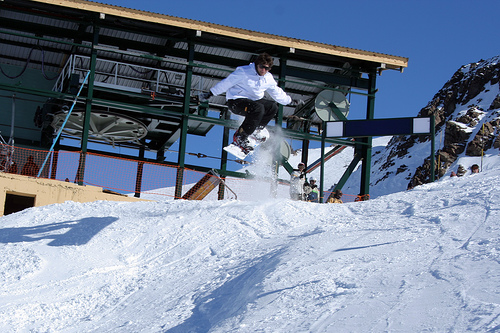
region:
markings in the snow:
[156, 198, 451, 331]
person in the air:
[211, 61, 301, 173]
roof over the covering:
[84, 0, 403, 62]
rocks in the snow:
[426, 73, 496, 176]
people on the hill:
[295, 161, 357, 218]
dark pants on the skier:
[227, 105, 269, 133]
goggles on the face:
[258, 65, 269, 74]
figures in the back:
[1, 146, 64, 182]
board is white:
[231, 130, 283, 156]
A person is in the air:
[185, 35, 286, 275]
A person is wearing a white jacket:
[196, 31, 303, 147]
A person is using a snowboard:
[187, 37, 279, 182]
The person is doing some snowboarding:
[185, 32, 290, 307]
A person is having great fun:
[186, 22, 286, 322]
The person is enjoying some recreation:
[195, 13, 287, 324]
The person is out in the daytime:
[178, 27, 283, 324]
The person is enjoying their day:
[196, 30, 286, 331]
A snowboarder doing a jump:
[200, 47, 305, 159]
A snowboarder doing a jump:
[196, 48, 306, 163]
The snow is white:
[13, 216, 498, 310]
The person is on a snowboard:
[201, 43, 304, 176]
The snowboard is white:
[219, 114, 286, 161]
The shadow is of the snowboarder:
[2, 190, 123, 267]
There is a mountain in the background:
[343, 50, 498, 175]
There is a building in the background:
[2, 0, 423, 221]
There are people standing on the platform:
[1, 137, 172, 207]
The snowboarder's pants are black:
[224, 89, 284, 155]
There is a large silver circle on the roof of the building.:
[44, 90, 170, 165]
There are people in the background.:
[272, 137, 456, 229]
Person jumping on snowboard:
[206, 50, 295, 160]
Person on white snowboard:
[207, 50, 296, 164]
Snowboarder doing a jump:
[207, 45, 307, 166]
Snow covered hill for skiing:
[9, 197, 497, 322]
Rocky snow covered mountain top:
[383, 54, 498, 186]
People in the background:
[0, 136, 60, 185]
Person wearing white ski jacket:
[203, 45, 297, 162]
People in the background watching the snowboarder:
[288, 160, 352, 204]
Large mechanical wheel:
[49, 106, 152, 153]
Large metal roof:
[12, 0, 409, 127]